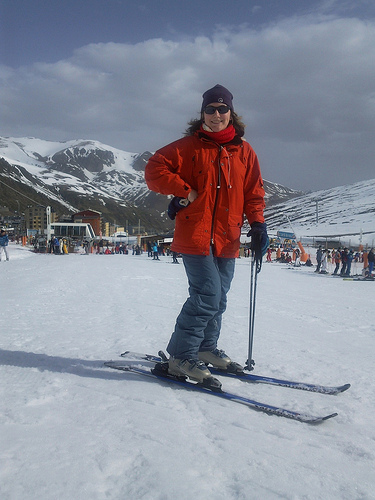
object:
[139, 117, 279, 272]
jacket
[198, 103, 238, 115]
sunglasses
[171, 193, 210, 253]
pocket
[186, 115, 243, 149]
scarf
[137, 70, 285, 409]
people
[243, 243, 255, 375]
poles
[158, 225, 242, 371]
pants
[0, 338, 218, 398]
shadow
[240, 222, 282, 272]
hand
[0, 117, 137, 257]
mountains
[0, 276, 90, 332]
snow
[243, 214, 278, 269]
glove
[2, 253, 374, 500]
ground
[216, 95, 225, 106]
design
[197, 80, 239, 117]
hat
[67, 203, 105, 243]
building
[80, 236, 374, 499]
tracks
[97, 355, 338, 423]
ski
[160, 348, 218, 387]
foot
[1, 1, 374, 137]
clouds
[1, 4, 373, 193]
sky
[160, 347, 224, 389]
boots